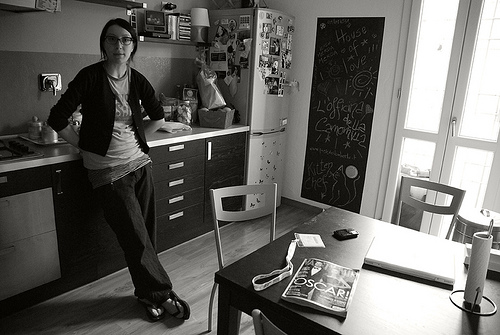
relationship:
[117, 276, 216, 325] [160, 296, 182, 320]
flip flops on woman's foot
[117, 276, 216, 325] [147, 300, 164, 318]
flip flops on woman's foot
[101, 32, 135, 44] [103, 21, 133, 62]
glasses on face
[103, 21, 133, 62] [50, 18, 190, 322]
face of woman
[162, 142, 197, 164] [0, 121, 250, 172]
drawer under counter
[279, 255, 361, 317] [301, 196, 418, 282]
magazine on table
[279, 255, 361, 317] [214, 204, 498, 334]
magazine on table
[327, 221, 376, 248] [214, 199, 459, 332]
cell phone on table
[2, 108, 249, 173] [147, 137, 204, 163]
drawer under counter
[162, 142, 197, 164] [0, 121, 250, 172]
drawer above counter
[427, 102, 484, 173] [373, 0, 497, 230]
handle on door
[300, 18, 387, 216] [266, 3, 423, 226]
chalkboard on wall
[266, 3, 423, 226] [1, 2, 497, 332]
wall of kitchen